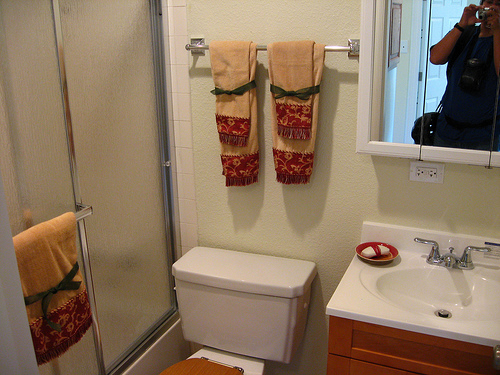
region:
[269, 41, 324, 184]
brown and dark red towel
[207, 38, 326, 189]
a set of towels with green ties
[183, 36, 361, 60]
a metal towel holder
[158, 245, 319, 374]
a while andbrown toilet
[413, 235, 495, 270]
two silver metal handles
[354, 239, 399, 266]
a red soap holder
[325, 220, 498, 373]
white and brown bathroom sink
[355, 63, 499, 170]
a white bathroom mirror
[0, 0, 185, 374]
a bathroom walk in shower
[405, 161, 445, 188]
a white receptacle outlet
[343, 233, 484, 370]
The sink is white.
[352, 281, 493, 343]
The sink is white.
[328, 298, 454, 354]
The sink is white.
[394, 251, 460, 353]
The sink is white.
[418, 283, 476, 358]
The sink is white.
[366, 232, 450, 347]
The sink is white.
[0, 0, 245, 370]
shower door made of glass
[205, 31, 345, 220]
towel is brown and red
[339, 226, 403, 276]
soap dish is brown and red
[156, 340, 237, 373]
the toilet lid is brown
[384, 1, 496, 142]
man is taking picture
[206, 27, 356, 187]
towels hanging above toilet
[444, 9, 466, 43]
man wearing a watch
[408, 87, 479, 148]
man carrying black bag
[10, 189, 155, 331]
towel hanging on shower door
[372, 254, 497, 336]
the sink is shiny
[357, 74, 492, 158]
A mirror is visible.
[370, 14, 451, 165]
A mirror is visible.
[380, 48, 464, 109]
A mirror is visible.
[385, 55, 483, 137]
A mirror is visible.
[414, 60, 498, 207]
A mirror is visible.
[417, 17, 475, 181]
A mirror is visible.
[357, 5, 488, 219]
A mirror is visible.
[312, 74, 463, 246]
A mirror is visible.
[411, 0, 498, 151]
reflection of a woman in the mirror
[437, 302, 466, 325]
a silver metal sink drain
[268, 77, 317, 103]
dark green ribbon around a towel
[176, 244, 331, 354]
white porcelain toilet tank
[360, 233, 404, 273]
a bar of white soap in a dish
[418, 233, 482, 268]
chrome faucet fixtures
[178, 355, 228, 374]
a wooden toiler seat lid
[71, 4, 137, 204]
an opaque glass shower door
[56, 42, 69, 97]
metal trim on the shower door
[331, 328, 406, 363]
a wood counter under a porcelain sink